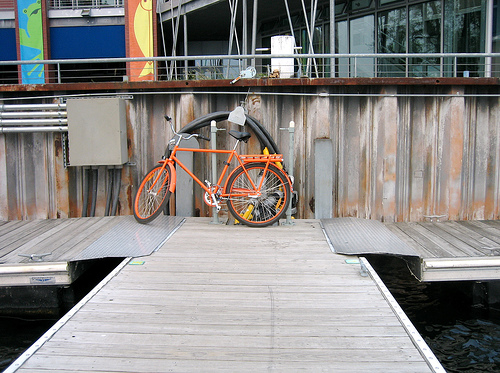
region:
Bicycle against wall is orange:
[130, 113, 290, 228]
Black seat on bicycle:
[227, 130, 251, 141]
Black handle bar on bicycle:
[162, 113, 170, 122]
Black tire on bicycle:
[135, 165, 174, 222]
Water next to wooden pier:
[370, 264, 498, 371]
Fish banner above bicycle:
[123, 0, 153, 83]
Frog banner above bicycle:
[15, 0, 47, 82]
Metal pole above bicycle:
[0, 50, 499, 65]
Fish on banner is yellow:
[130, 0, 154, 78]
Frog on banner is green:
[20, 0, 45, 79]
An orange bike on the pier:
[130, 115, 291, 224]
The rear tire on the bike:
[223, 159, 293, 227]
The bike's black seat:
[227, 127, 252, 144]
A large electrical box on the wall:
[64, 96, 131, 171]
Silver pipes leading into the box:
[0, 103, 70, 132]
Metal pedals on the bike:
[199, 176, 224, 213]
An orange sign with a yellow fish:
[122, 0, 158, 85]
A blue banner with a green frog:
[15, 0, 47, 83]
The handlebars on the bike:
[163, 113, 212, 142]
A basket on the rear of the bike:
[235, 151, 283, 165]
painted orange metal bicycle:
[130, 110, 295, 231]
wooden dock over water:
[1, 209, 497, 371]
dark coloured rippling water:
[368, 245, 498, 372]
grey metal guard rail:
[2, 41, 496, 88]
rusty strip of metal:
[1, 76, 498, 89]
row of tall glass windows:
[248, 2, 497, 84]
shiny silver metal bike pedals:
[197, 174, 231, 215]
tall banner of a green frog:
[10, 0, 48, 85]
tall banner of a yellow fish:
[122, 2, 155, 84]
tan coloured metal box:
[63, 92, 136, 172]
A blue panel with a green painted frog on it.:
[14, 0, 51, 87]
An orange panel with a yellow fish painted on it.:
[124, 0, 159, 82]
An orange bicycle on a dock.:
[132, 115, 293, 229]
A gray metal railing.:
[1, 51, 498, 84]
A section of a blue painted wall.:
[0, 23, 128, 64]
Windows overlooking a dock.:
[259, 2, 499, 77]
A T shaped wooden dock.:
[0, 215, 498, 370]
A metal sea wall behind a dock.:
[0, 75, 498, 230]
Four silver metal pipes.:
[1, 101, 76, 136]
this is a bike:
[134, 127, 296, 267]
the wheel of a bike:
[226, 156, 300, 238]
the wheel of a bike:
[134, 159, 186, 227]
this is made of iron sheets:
[304, 75, 388, 207]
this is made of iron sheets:
[4, 141, 62, 222]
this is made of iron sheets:
[292, 94, 376, 218]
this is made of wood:
[241, 267, 351, 351]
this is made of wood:
[151, 285, 238, 372]